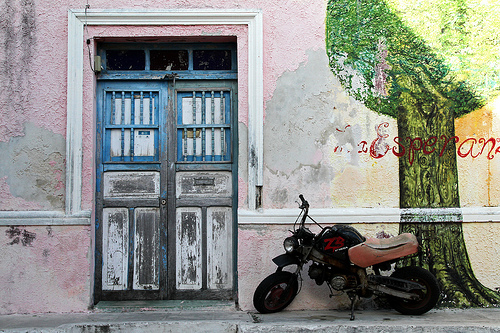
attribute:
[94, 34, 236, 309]
doors — very old, wooden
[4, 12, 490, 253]
building — pink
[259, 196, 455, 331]
motorcycle — black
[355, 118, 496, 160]
word — red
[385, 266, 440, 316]
wheel — the rear wheel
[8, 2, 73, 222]
wall — gray, pink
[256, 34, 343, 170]
wall — pink, gray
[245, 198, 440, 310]
motorbike — parked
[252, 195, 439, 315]
bike — dirt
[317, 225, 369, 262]
logo — red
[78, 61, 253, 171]
rails — blue